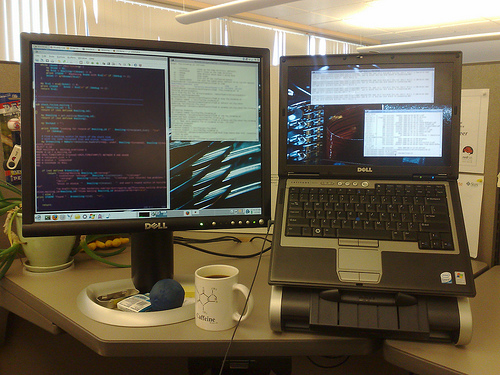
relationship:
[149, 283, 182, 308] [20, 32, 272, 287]
ball under monitor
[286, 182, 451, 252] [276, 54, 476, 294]
keyboard on laptop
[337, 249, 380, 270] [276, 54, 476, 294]
touch pad on laptop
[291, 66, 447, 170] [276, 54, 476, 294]
screen on laptop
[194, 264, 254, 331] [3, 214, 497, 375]
coffee cup on a desk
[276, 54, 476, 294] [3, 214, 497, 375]
laptop on desk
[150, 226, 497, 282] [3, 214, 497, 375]
wires on a desk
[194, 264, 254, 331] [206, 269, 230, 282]
coffee cup filled with coffee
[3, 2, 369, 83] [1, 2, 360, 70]
blinds covering a window